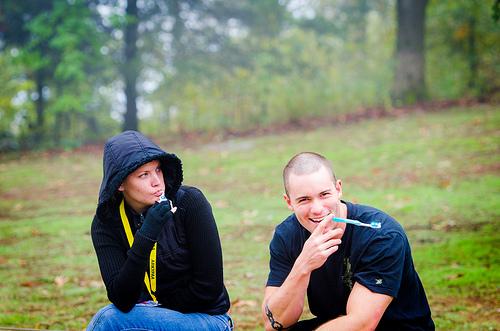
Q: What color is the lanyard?
A: Yellow.